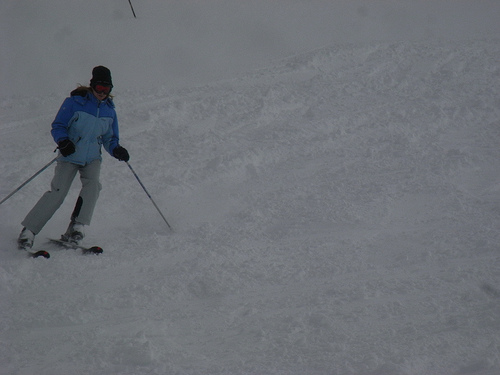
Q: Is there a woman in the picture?
A: Yes, there is a woman.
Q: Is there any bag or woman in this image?
A: Yes, there is a woman.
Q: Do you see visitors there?
A: No, there are no visitors.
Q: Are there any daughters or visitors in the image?
A: No, there are no visitors or daughters.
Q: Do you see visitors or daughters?
A: No, there are no visitors or daughters.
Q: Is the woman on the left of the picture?
A: Yes, the woman is on the left of the image.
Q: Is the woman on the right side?
A: No, the woman is on the left of the image.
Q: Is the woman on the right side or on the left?
A: The woman is on the left of the image.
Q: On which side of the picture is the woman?
A: The woman is on the left of the image.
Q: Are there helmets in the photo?
A: No, there are no helmets.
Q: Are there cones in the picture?
A: No, there are no cones.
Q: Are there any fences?
A: No, there are no fences.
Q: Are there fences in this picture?
A: No, there are no fences.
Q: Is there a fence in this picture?
A: No, there are no fences.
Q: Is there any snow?
A: Yes, there is snow.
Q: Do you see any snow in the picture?
A: Yes, there is snow.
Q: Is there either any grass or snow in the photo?
A: Yes, there is snow.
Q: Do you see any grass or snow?
A: Yes, there is snow.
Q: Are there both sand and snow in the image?
A: No, there is snow but no sand.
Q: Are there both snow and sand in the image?
A: No, there is snow but no sand.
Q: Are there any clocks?
A: No, there are no clocks.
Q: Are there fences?
A: No, there are no fences.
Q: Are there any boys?
A: No, there are no boys.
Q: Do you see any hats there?
A: Yes, there is a hat.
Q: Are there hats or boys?
A: Yes, there is a hat.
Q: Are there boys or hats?
A: Yes, there is a hat.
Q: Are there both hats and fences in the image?
A: No, there is a hat but no fences.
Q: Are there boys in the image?
A: No, there are no boys.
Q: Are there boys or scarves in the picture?
A: No, there are no boys or scarves.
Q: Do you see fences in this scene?
A: No, there are no fences.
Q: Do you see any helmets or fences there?
A: No, there are no fences or helmets.